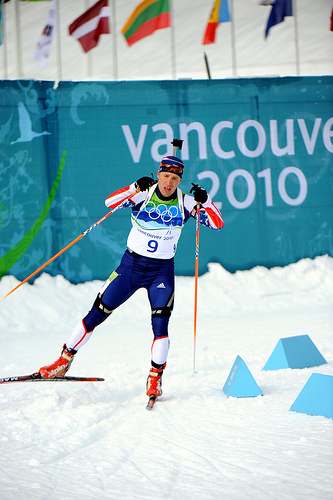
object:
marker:
[260, 333, 326, 373]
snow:
[62, 438, 80, 458]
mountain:
[196, 0, 333, 70]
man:
[35, 154, 223, 401]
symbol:
[135, 227, 174, 254]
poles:
[192, 201, 200, 379]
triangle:
[263, 335, 329, 370]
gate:
[0, 91, 333, 180]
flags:
[67, 0, 116, 55]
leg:
[38, 283, 132, 382]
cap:
[159, 154, 185, 179]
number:
[145, 240, 158, 254]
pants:
[83, 251, 174, 336]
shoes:
[37, 344, 79, 384]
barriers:
[222, 354, 265, 396]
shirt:
[104, 181, 223, 265]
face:
[159, 172, 180, 198]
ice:
[185, 445, 194, 456]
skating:
[0, 333, 173, 412]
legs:
[143, 296, 174, 405]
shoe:
[143, 336, 171, 403]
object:
[287, 370, 333, 421]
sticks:
[0, 289, 19, 313]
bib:
[126, 199, 183, 258]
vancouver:
[120, 113, 333, 163]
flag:
[120, 0, 174, 46]